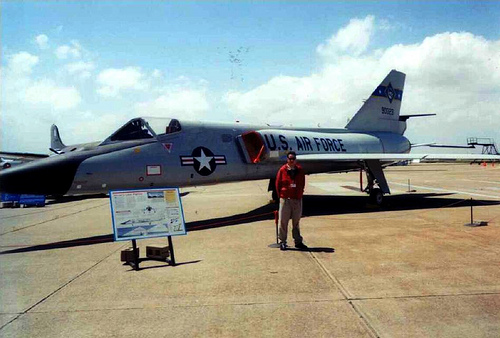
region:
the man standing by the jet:
[266, 153, 307, 255]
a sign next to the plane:
[106, 188, 184, 238]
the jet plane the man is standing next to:
[1, 65, 496, 192]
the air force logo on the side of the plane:
[181, 142, 229, 174]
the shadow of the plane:
[182, 187, 499, 222]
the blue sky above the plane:
[4, 3, 497, 58]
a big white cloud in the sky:
[254, 25, 499, 146]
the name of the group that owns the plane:
[261, 129, 352, 153]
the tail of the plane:
[346, 70, 420, 145]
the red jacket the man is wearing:
[273, 159, 307, 200]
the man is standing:
[279, 150, 305, 257]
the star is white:
[196, 148, 213, 173]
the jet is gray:
[88, 165, 123, 178]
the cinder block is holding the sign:
[146, 242, 171, 259]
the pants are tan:
[279, 208, 287, 222]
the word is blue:
[311, 134, 336, 151]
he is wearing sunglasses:
[286, 155, 298, 162]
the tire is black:
[366, 186, 386, 205]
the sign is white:
[127, 202, 173, 226]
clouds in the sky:
[185, 53, 319, 121]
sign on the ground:
[105, 195, 192, 263]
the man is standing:
[254, 161, 336, 259]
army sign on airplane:
[158, 135, 231, 172]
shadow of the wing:
[323, 189, 479, 216]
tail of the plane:
[352, 67, 405, 138]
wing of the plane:
[307, 150, 489, 167]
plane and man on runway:
[28, 113, 458, 233]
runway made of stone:
[332, 269, 430, 317]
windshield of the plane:
[87, 110, 172, 140]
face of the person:
[266, 141, 312, 165]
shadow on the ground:
[308, 236, 356, 273]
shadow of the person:
[303, 233, 373, 270]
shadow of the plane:
[197, 204, 242, 239]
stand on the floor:
[120, 255, 145, 275]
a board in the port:
[97, 180, 209, 245]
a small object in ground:
[456, 181, 499, 236]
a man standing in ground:
[271, 146, 341, 276]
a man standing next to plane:
[255, 140, 348, 268]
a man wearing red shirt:
[270, 148, 314, 195]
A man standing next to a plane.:
[263, 144, 310, 256]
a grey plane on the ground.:
[0, 51, 487, 240]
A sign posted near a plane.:
[104, 185, 196, 280]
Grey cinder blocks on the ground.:
[114, 242, 173, 265]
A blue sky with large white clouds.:
[1, 0, 496, 149]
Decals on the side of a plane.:
[182, 80, 404, 177]